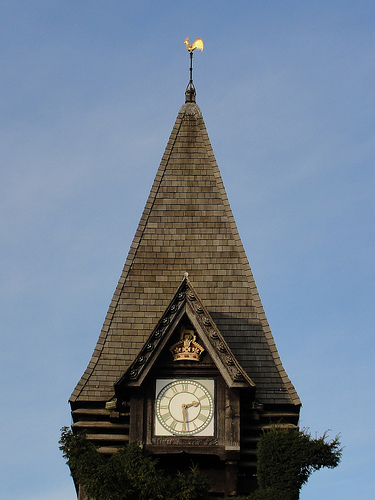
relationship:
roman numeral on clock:
[192, 384, 198, 395] [150, 375, 216, 439]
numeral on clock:
[197, 414, 207, 422] [150, 375, 216, 439]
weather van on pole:
[179, 33, 203, 53] [187, 49, 193, 82]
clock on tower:
[150, 375, 216, 439] [57, 34, 344, 496]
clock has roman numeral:
[150, 375, 216, 439] [180, 382, 187, 391]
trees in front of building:
[60, 420, 124, 498] [66, 34, 302, 497]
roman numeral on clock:
[180, 382, 187, 391] [150, 375, 216, 439]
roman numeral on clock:
[180, 382, 187, 391] [151, 372, 220, 439]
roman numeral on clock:
[180, 382, 187, 391] [156, 380, 213, 435]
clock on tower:
[150, 375, 216, 439] [68, 35, 302, 498]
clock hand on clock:
[181, 402, 186, 434] [156, 380, 213, 435]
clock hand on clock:
[182, 399, 201, 406] [156, 380, 213, 435]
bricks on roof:
[170, 196, 232, 261] [65, 84, 321, 434]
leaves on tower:
[257, 426, 343, 498] [68, 35, 302, 498]